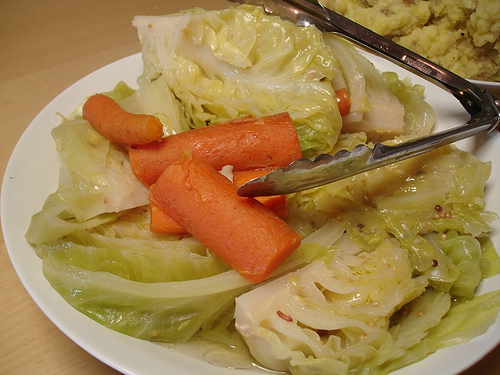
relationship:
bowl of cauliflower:
[319, 0, 500, 100] [353, 1, 430, 34]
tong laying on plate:
[238, 0, 499, 198] [1, 43, 498, 374]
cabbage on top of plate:
[38, 240, 319, 344] [1, 43, 498, 374]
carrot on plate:
[128, 111, 303, 187] [1, 43, 498, 374]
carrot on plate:
[148, 165, 289, 234] [1, 43, 498, 374]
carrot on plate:
[81, 92, 163, 144] [1, 43, 498, 374]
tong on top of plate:
[238, 0, 499, 198] [1, 43, 498, 374]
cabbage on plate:
[54, 76, 193, 221] [1, 43, 498, 374]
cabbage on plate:
[132, 5, 343, 163] [1, 43, 498, 374]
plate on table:
[1, 43, 498, 374] [0, 0, 499, 373]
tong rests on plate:
[238, 0, 499, 198] [1, 43, 498, 374]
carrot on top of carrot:
[151, 150, 302, 284] [148, 165, 289, 234]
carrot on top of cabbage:
[128, 111, 303, 187] [54, 76, 193, 221]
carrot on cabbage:
[151, 150, 302, 284] [38, 240, 319, 344]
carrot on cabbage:
[81, 92, 163, 144] [54, 76, 193, 221]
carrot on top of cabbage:
[128, 111, 303, 187] [132, 5, 343, 163]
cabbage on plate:
[327, 35, 436, 167] [1, 43, 498, 374]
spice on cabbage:
[434, 205, 441, 213] [374, 159, 499, 287]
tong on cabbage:
[238, 0, 499, 198] [327, 35, 436, 167]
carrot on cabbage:
[335, 88, 352, 116] [327, 35, 436, 167]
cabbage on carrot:
[132, 5, 343, 163] [335, 88, 352, 116]